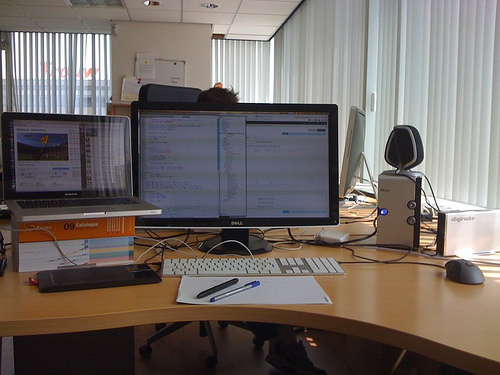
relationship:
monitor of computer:
[129, 103, 338, 225] [127, 103, 350, 276]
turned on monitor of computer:
[129, 103, 338, 225] [127, 103, 350, 276]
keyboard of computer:
[162, 257, 345, 275] [127, 103, 350, 276]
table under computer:
[1, 223, 496, 333] [127, 103, 350, 276]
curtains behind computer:
[220, 36, 498, 203] [127, 103, 350, 276]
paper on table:
[183, 275, 324, 307] [1, 223, 496, 333]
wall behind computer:
[117, 20, 212, 100] [127, 103, 350, 276]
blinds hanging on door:
[3, 33, 108, 116] [3, 32, 112, 117]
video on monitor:
[15, 132, 69, 163] [3, 118, 126, 198]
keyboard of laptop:
[17, 196, 144, 210] [0, 112, 160, 218]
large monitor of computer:
[129, 103, 338, 225] [127, 103, 350, 276]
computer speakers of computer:
[373, 124, 423, 251] [127, 103, 350, 276]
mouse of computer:
[444, 258, 485, 286] [127, 103, 350, 276]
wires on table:
[146, 230, 227, 259] [1, 223, 496, 333]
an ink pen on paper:
[196, 277, 260, 302] [183, 275, 324, 307]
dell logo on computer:
[228, 220, 248, 228] [127, 103, 350, 276]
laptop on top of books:
[0, 112, 160, 218] [10, 217, 139, 267]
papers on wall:
[130, 52, 156, 81] [117, 20, 212, 100]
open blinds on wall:
[3, 33, 108, 116] [5, 31, 265, 117]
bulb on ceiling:
[145, 1, 161, 8] [3, 2, 288, 42]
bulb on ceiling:
[200, 1, 223, 13] [3, 2, 288, 42]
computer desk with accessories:
[1, 223, 496, 333] [25, 226, 487, 293]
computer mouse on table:
[444, 258, 485, 286] [1, 223, 496, 333]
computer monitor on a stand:
[129, 103, 338, 225] [200, 227, 276, 255]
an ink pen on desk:
[196, 277, 260, 302] [1, 223, 496, 333]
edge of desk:
[5, 314, 184, 334] [1, 223, 496, 333]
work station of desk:
[8, 106, 485, 289] [1, 223, 496, 333]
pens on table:
[197, 277, 260, 301] [1, 223, 496, 333]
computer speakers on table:
[380, 125, 422, 244] [1, 223, 496, 333]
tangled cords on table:
[146, 230, 227, 259] [1, 223, 496, 333]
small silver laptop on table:
[0, 112, 160, 218] [1, 223, 496, 333]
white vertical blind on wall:
[3, 33, 108, 116] [5, 31, 265, 117]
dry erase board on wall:
[136, 59, 187, 88] [117, 20, 212, 100]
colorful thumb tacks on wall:
[136, 76, 144, 85] [117, 20, 212, 100]